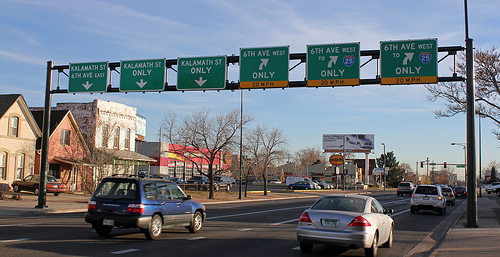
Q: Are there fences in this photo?
A: No, there are no fences.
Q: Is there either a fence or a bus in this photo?
A: No, there are no fences or buses.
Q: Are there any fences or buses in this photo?
A: No, there are no fences or buses.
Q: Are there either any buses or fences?
A: No, there are no fences or buses.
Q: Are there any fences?
A: No, there are no fences.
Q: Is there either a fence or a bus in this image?
A: No, there are no fences or buses.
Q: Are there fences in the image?
A: No, there are no fences.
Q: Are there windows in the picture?
A: Yes, there is a window.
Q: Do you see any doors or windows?
A: Yes, there is a window.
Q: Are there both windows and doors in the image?
A: No, there is a window but no doors.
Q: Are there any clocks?
A: No, there are no clocks.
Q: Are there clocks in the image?
A: No, there are no clocks.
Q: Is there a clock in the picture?
A: No, there are no clocks.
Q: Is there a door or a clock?
A: No, there are no clocks or doors.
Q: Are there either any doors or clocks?
A: No, there are no clocks or doors.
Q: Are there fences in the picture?
A: No, there are no fences.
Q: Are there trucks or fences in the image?
A: No, there are no fences or trucks.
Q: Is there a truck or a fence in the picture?
A: No, there are no fences or trucks.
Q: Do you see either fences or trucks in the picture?
A: No, there are no fences or trucks.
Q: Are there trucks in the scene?
A: No, there are no trucks.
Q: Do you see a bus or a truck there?
A: No, there are no trucks or buses.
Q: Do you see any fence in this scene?
A: No, there are no fences.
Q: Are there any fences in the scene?
A: No, there are no fences.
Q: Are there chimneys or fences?
A: No, there are no fences or chimneys.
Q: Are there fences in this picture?
A: No, there are no fences.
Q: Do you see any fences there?
A: No, there are no fences.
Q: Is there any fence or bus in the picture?
A: No, there are no fences or buses.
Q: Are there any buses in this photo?
A: No, there are no buses.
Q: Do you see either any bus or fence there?
A: No, there are no buses or fences.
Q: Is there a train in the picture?
A: No, there are no trains.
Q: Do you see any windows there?
A: Yes, there is a window.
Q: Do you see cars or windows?
A: Yes, there is a window.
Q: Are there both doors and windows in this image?
A: No, there is a window but no doors.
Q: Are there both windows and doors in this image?
A: No, there is a window but no doors.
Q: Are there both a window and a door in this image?
A: No, there is a window but no doors.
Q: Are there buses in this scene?
A: No, there are no buses.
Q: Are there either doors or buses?
A: No, there are no buses or doors.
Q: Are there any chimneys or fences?
A: No, there are no fences or chimneys.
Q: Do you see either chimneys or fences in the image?
A: No, there are no fences or chimneys.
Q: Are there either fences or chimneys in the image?
A: No, there are no fences or chimneys.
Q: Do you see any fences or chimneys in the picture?
A: No, there are no fences or chimneys.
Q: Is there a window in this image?
A: Yes, there is a window.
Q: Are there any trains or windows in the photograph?
A: Yes, there is a window.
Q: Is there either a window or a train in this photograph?
A: Yes, there is a window.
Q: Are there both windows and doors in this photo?
A: No, there is a window but no doors.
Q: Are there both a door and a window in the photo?
A: No, there is a window but no doors.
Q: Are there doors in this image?
A: No, there are no doors.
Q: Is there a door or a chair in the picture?
A: No, there are no doors or chairs.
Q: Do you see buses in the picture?
A: No, there are no buses.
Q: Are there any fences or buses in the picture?
A: No, there are no buses or fences.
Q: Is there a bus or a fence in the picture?
A: No, there are no buses or fences.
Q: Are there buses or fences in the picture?
A: No, there are no buses or fences.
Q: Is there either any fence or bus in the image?
A: No, there are no buses or fences.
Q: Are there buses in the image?
A: No, there are no buses.